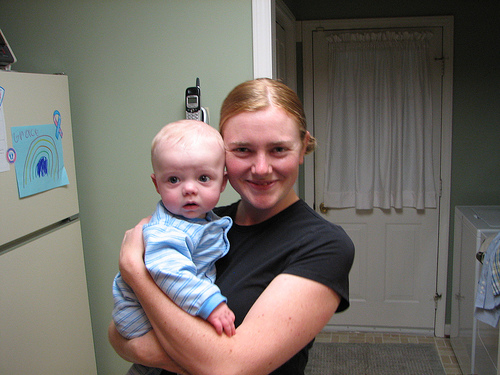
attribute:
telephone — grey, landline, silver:
[184, 77, 203, 118]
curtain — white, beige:
[330, 32, 438, 208]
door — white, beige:
[311, 32, 439, 338]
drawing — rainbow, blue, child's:
[9, 127, 71, 197]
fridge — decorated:
[1, 70, 96, 374]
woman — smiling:
[218, 81, 356, 373]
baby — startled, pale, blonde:
[115, 118, 235, 362]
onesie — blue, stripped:
[140, 202, 231, 320]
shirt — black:
[211, 199, 354, 374]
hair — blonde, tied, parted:
[219, 76, 306, 136]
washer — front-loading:
[446, 203, 497, 371]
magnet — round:
[5, 146, 16, 164]